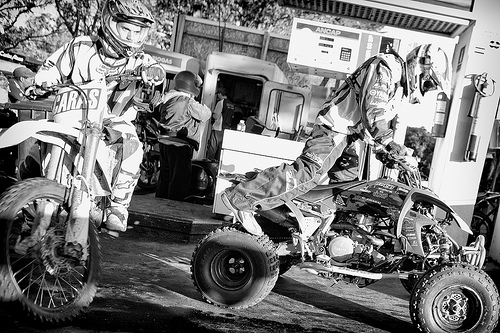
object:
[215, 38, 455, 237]
rider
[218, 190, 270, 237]
foot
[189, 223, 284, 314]
tire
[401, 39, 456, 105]
helmet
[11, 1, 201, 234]
man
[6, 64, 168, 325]
dirtbike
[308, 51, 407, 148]
jersey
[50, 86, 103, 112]
sticker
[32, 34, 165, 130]
jacket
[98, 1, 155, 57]
helmet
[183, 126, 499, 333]
motorcycle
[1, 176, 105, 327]
wheel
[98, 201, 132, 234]
shoes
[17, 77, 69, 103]
handle bars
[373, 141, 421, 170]
handle bars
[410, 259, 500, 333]
tire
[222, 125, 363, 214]
pants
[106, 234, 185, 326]
road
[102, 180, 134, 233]
boots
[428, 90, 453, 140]
fire extinguisher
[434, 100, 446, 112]
label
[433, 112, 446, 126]
label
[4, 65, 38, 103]
man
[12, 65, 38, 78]
hat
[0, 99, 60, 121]
fence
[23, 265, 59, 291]
spokes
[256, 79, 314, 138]
door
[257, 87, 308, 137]
window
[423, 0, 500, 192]
wall